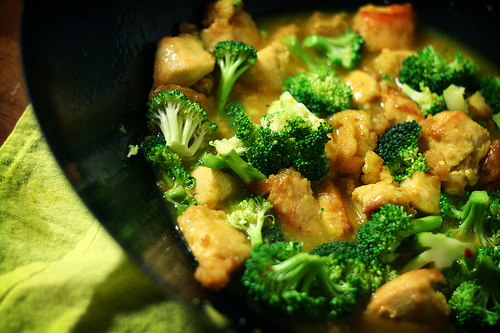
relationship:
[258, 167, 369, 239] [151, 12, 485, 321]
chicken in sauce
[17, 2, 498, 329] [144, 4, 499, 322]
bowl holding food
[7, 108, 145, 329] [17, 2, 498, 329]
towel underneath bowl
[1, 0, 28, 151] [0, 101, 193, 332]
wooden table underneath towel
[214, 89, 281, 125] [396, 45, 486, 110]
sauce bathing broccoli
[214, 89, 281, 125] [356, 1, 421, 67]
sauce bathing chicken